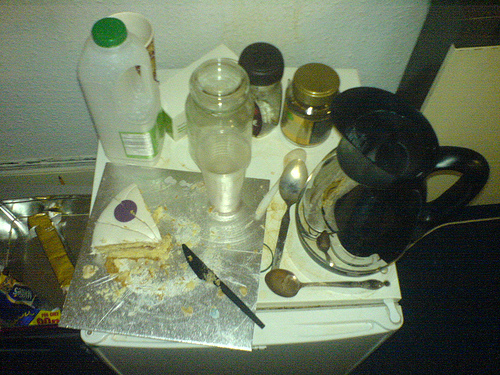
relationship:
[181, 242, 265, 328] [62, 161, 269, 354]
knife on top of tray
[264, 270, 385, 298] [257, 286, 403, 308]
spoon on fridge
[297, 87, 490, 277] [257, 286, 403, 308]
kettle on fridge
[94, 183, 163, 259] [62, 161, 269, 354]
cake on tray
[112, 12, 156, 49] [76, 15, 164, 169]
cup behind bottle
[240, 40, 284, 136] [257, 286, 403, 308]
bottle on fridge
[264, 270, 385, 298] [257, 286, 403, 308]
spoon laying on fridge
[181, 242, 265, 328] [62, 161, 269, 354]
knife on tray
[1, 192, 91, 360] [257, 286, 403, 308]
sink beside fridge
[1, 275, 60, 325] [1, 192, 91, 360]
paper inside sink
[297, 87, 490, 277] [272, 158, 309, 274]
kettle beside spoon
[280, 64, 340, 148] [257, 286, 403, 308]
bottle on fridge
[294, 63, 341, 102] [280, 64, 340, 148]
lid on bottle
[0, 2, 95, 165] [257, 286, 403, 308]
wall behind fridge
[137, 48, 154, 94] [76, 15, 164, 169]
handle of bottle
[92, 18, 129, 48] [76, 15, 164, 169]
cap on bottle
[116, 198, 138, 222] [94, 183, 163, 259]
circle on cake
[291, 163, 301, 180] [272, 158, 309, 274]
light on spoon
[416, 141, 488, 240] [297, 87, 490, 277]
handle on kettle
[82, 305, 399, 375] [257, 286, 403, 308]
door of fridge